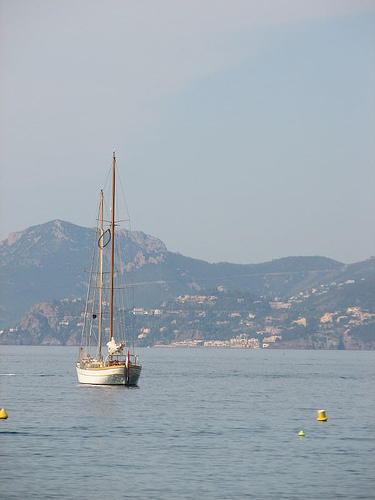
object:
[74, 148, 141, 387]
boat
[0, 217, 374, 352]
mountains